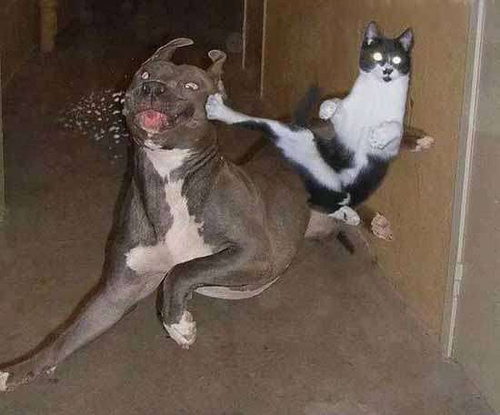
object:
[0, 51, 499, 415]
ground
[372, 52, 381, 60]
eyes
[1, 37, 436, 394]
dog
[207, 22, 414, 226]
cat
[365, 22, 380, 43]
ears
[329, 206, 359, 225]
paw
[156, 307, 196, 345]
paw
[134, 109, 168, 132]
mouth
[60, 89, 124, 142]
spit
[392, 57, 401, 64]
light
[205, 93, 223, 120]
foot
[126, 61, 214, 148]
face